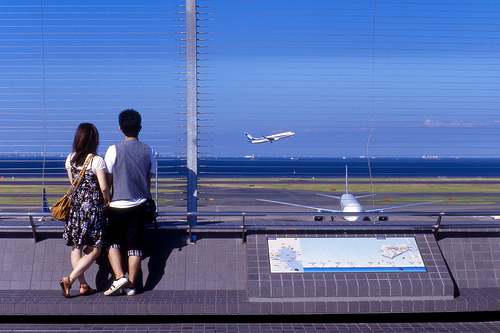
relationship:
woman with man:
[42, 108, 116, 298] [99, 99, 182, 272]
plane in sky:
[242, 115, 307, 162] [65, 9, 264, 96]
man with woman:
[99, 99, 182, 272] [42, 108, 116, 298]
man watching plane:
[99, 99, 182, 272] [242, 115, 307, 162]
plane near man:
[242, 115, 307, 162] [99, 99, 182, 272]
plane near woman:
[242, 115, 307, 162] [42, 108, 116, 298]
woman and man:
[42, 108, 116, 298] [99, 99, 182, 272]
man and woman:
[99, 99, 182, 272] [42, 108, 116, 298]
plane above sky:
[242, 115, 307, 162] [65, 9, 264, 96]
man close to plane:
[99, 99, 182, 272] [242, 115, 307, 162]